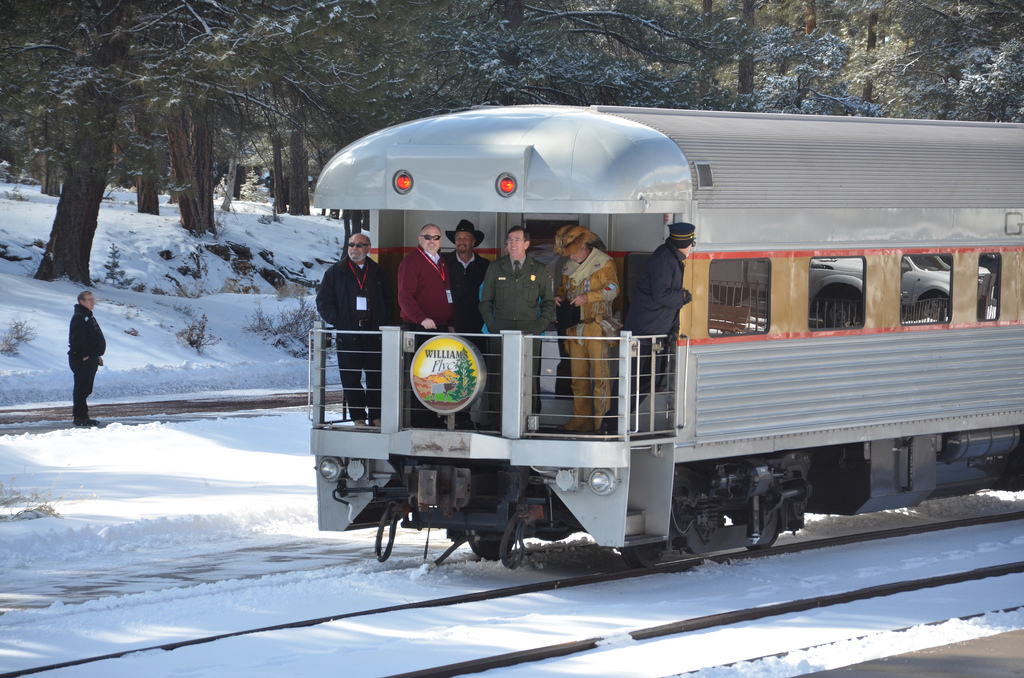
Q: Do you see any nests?
A: No, there are no nests.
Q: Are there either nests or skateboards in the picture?
A: No, there are no nests or skateboards.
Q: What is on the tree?
A: The leaves are on the tree.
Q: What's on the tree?
A: The leaves are on the tree.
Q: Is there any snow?
A: Yes, there is snow.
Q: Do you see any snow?
A: Yes, there is snow.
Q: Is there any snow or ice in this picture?
A: Yes, there is snow.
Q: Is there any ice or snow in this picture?
A: Yes, there is snow.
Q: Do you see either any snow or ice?
A: Yes, there is snow.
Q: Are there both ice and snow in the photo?
A: No, there is snow but no ice.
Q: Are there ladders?
A: No, there are no ladders.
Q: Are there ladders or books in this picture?
A: No, there are no ladders or books.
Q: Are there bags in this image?
A: No, there are no bags.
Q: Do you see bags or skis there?
A: No, there are no bags or skis.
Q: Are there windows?
A: Yes, there is a window.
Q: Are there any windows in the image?
A: Yes, there is a window.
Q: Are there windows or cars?
A: Yes, there is a window.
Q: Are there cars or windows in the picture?
A: Yes, there is a window.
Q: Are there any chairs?
A: No, there are no chairs.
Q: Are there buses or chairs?
A: No, there are no chairs or buses.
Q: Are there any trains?
A: Yes, there is a train.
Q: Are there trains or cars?
A: Yes, there is a train.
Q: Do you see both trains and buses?
A: No, there is a train but no buses.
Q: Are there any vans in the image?
A: No, there are no vans.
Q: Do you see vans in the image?
A: No, there are no vans.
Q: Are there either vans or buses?
A: No, there are no vans or buses.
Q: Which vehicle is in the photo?
A: The vehicle is a train.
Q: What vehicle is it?
A: The vehicle is a train.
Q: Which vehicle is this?
A: This is a train.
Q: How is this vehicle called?
A: This is a train.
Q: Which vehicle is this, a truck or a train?
A: This is a train.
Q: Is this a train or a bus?
A: This is a train.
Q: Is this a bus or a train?
A: This is a train.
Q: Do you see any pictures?
A: No, there are no pictures.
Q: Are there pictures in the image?
A: No, there are no pictures.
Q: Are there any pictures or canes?
A: No, there are no pictures or canes.